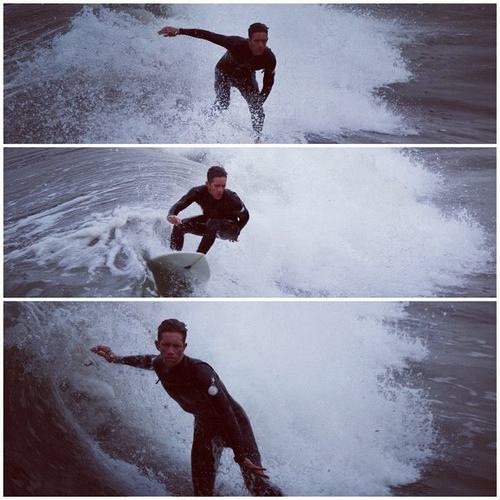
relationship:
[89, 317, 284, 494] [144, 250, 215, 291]
man standing on a surfboard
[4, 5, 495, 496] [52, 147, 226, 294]
ocean water with wave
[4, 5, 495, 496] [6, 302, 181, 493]
ocean water with wave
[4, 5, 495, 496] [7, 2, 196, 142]
ocean water with wave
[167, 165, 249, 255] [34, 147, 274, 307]
man riding a wave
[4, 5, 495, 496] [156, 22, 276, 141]
ocean water splashing around surfer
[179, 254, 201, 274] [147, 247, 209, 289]
design under surfboard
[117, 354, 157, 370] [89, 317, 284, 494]
arm of man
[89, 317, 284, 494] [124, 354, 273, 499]
man in suit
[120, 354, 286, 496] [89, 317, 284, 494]
black suit on man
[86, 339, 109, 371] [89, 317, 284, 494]
right hand on man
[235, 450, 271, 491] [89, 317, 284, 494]
left hand on man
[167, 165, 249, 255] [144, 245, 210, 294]
man on surf board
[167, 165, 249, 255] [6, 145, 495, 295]
man surfing in water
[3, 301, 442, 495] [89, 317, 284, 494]
wave behind man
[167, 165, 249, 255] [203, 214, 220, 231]
man bending h knee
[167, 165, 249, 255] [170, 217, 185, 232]
man bending h knee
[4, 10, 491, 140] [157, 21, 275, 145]
wave crashing around man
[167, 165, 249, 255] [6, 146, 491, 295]
man surfing along side of a wave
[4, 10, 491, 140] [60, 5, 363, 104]
wave creating water spray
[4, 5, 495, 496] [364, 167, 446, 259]
ocean water on wave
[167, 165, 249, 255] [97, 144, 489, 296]
man moves with wave